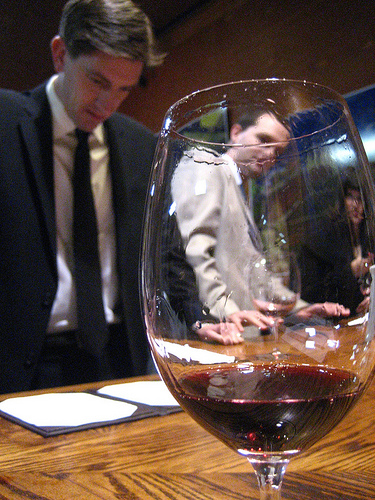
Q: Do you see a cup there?
A: No, there are no cups.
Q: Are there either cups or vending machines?
A: No, there are no cups or vending machines.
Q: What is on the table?
A: The glass is on the table.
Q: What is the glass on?
A: The glass is on the table.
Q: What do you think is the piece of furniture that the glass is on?
A: The piece of furniture is a table.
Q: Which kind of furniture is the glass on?
A: The glass is on the table.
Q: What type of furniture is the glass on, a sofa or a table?
A: The glass is on a table.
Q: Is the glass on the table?
A: Yes, the glass is on the table.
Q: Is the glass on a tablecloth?
A: No, the glass is on the table.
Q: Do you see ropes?
A: No, there are no ropes.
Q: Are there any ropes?
A: No, there are no ropes.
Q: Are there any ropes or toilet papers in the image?
A: No, there are no ropes or toilet papers.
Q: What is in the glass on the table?
A: The liquid is in the glass.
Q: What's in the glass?
A: The liquid is in the glass.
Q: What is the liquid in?
A: The liquid is in the glass.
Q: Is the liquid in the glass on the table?
A: Yes, the liquid is in the glass.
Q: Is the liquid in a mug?
A: No, the liquid is in the glass.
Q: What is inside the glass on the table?
A: The liquid is inside the glass.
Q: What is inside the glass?
A: The liquid is inside the glass.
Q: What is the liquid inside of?
A: The liquid is inside the glass.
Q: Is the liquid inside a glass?
A: Yes, the liquid is inside a glass.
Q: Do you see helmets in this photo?
A: No, there are no helmets.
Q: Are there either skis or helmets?
A: No, there are no helmets or skis.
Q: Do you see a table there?
A: Yes, there is a table.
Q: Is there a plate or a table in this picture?
A: Yes, there is a table.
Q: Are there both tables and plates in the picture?
A: No, there is a table but no plates.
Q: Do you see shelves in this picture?
A: No, there are no shelves.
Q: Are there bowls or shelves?
A: No, there are no shelves or bowls.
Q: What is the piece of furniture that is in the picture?
A: The piece of furniture is a table.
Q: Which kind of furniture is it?
A: The piece of furniture is a table.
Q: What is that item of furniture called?
A: This is a table.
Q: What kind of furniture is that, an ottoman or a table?
A: This is a table.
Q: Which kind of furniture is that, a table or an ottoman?
A: This is a table.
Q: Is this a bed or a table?
A: This is a table.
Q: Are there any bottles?
A: No, there are no bottles.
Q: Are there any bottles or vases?
A: No, there are no bottles or vases.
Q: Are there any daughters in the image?
A: No, there are no daughters.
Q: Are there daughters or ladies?
A: No, there are no daughters or ladies.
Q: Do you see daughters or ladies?
A: No, there are no daughters or ladies.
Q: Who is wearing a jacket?
A: The man is wearing a jacket.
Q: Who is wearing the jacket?
A: The man is wearing a jacket.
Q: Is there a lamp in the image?
A: No, there are no lamps.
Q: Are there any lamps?
A: No, there are no lamps.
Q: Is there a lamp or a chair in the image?
A: No, there are no lamps or chairs.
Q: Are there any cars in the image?
A: No, there are no cars.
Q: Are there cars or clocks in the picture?
A: No, there are no cars or clocks.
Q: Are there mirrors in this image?
A: No, there are no mirrors.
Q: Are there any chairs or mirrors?
A: No, there are no mirrors or chairs.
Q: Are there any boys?
A: No, there are no boys.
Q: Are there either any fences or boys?
A: No, there are no boys or fences.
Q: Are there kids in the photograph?
A: No, there are no kids.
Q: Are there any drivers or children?
A: No, there are no children or drivers.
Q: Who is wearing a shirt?
A: The man is wearing a shirt.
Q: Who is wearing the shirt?
A: The man is wearing a shirt.